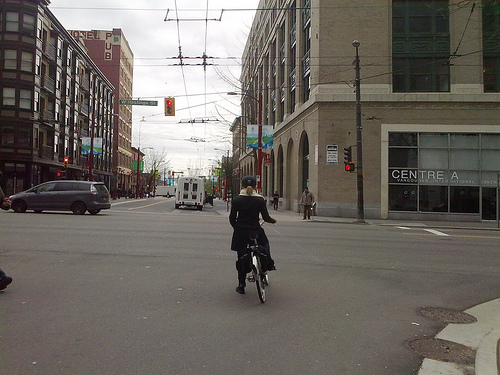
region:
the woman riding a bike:
[212, 172, 297, 318]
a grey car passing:
[19, 175, 128, 232]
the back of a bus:
[175, 175, 210, 219]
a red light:
[160, 97, 171, 103]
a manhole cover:
[420, 291, 478, 348]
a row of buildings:
[18, 9, 160, 181]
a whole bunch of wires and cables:
[158, 17, 234, 175]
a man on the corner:
[294, 185, 321, 230]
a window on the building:
[2, 6, 20, 47]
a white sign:
[389, 167, 469, 194]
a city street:
[10, 4, 475, 363]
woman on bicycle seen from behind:
[216, 168, 280, 308]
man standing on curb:
[292, 175, 334, 226]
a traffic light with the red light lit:
[155, 90, 179, 126]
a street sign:
[106, 90, 163, 118]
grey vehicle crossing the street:
[6, 171, 203, 227]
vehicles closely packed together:
[0, 3, 155, 227]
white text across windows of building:
[361, 108, 492, 194]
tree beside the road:
[135, 136, 166, 206]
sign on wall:
[316, 126, 347, 177]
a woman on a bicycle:
[221, 171, 282, 308]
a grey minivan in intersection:
[6, 174, 114, 216]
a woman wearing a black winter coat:
[226, 174, 281, 304]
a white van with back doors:
[171, 172, 206, 212]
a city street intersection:
[2, 201, 425, 369]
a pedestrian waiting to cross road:
[296, 183, 318, 222]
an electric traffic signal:
[162, 94, 179, 123]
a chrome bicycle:
[242, 236, 274, 304]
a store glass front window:
[385, 131, 497, 220]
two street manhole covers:
[404, 299, 479, 368]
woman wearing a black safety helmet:
[199, 162, 304, 335]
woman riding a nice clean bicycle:
[187, 161, 303, 331]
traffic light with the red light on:
[103, 77, 239, 209]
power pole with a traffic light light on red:
[302, 31, 401, 261]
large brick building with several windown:
[212, 48, 478, 208]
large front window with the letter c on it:
[345, 121, 468, 236]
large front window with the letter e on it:
[359, 148, 471, 213]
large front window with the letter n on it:
[377, 148, 481, 205]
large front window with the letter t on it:
[355, 152, 467, 214]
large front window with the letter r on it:
[362, 163, 464, 204]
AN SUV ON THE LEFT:
[3, 176, 115, 218]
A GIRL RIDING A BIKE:
[212, 176, 287, 310]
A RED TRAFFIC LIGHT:
[339, 138, 358, 180]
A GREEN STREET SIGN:
[110, 91, 159, 115]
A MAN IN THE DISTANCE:
[294, 183, 321, 223]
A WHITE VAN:
[166, 174, 213, 217]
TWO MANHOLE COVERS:
[394, 293, 487, 374]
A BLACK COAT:
[225, 196, 281, 258]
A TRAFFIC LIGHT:
[329, 140, 365, 187]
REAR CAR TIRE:
[64, 196, 94, 218]